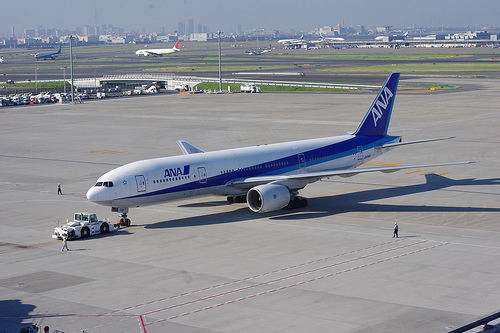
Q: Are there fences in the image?
A: No, there are no fences.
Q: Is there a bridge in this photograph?
A: Yes, there is a bridge.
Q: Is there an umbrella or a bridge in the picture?
A: Yes, there is a bridge.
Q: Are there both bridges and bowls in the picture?
A: No, there is a bridge but no bowls.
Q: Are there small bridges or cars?
A: Yes, there is a small bridge.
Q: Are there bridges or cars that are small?
A: Yes, the bridge is small.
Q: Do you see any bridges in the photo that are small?
A: Yes, there is a small bridge.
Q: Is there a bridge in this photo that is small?
A: Yes, there is a bridge that is small.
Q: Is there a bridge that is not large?
A: Yes, there is a small bridge.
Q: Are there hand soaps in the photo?
A: No, there are no hand soaps.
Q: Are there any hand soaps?
A: No, there are no hand soaps.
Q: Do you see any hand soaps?
A: No, there are no hand soaps.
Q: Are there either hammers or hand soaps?
A: No, there are no hand soaps or hammers.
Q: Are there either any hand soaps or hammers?
A: No, there are no hand soaps or hammers.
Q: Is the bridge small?
A: Yes, the bridge is small.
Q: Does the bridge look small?
A: Yes, the bridge is small.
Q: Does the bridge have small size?
A: Yes, the bridge is small.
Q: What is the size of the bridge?
A: The bridge is small.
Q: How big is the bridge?
A: The bridge is small.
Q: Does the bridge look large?
A: No, the bridge is small.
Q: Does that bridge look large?
A: No, the bridge is small.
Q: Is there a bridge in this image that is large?
A: No, there is a bridge but it is small.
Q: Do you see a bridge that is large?
A: No, there is a bridge but it is small.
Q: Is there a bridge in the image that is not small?
A: No, there is a bridge but it is small.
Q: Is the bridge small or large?
A: The bridge is small.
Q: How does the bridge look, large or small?
A: The bridge is small.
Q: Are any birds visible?
A: No, there are no birds.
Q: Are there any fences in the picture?
A: No, there are no fences.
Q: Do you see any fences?
A: No, there are no fences.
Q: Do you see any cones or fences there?
A: No, there are no fences or cones.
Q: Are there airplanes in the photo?
A: Yes, there is an airplane.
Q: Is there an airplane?
A: Yes, there is an airplane.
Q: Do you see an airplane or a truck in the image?
A: Yes, there is an airplane.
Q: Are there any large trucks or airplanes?
A: Yes, there is a large airplane.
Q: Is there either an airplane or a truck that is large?
A: Yes, the airplane is large.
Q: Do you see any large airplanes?
A: Yes, there is a large airplane.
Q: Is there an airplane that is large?
A: Yes, there is an airplane that is large.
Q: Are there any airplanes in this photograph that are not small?
A: Yes, there is a large airplane.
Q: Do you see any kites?
A: No, there are no kites.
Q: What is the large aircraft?
A: The aircraft is an airplane.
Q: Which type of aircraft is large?
A: The aircraft is an airplane.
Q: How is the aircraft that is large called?
A: The aircraft is an airplane.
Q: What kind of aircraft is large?
A: The aircraft is an airplane.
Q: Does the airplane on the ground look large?
A: Yes, the airplane is large.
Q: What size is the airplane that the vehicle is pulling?
A: The airplane is large.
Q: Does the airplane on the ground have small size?
A: No, the plane is large.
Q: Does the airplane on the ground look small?
A: No, the plane is large.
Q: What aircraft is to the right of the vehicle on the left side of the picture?
A: The aircraft is an airplane.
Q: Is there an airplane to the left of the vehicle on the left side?
A: No, the airplane is to the right of the vehicle.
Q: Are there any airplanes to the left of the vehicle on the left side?
A: No, the airplane is to the right of the vehicle.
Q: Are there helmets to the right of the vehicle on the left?
A: No, there is an airplane to the right of the vehicle.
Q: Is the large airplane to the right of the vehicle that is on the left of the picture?
A: Yes, the plane is to the right of the vehicle.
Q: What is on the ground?
A: The airplane is on the ground.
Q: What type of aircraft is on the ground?
A: The aircraft is an airplane.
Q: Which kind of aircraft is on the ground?
A: The aircraft is an airplane.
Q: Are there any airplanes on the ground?
A: Yes, there is an airplane on the ground.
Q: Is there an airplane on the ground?
A: Yes, there is an airplane on the ground.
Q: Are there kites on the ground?
A: No, there is an airplane on the ground.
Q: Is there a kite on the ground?
A: No, there is an airplane on the ground.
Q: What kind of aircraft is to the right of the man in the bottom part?
A: The aircraft is an airplane.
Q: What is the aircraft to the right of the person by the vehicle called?
A: The aircraft is an airplane.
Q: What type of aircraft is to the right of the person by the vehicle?
A: The aircraft is an airplane.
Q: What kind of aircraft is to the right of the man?
A: The aircraft is an airplane.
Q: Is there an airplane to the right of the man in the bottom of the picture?
A: Yes, there is an airplane to the right of the man.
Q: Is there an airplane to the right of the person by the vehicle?
A: Yes, there is an airplane to the right of the man.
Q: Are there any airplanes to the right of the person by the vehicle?
A: Yes, there is an airplane to the right of the man.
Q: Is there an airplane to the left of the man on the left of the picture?
A: No, the airplane is to the right of the man.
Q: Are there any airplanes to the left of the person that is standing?
A: No, the airplane is to the right of the man.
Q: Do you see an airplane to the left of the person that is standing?
A: No, the airplane is to the right of the man.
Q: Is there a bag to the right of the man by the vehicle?
A: No, there is an airplane to the right of the man.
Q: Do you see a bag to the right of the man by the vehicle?
A: No, there is an airplane to the right of the man.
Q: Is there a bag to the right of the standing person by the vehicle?
A: No, there is an airplane to the right of the man.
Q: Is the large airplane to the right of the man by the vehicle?
A: Yes, the airplane is to the right of the man.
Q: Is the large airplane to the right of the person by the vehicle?
A: Yes, the airplane is to the right of the man.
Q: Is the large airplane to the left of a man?
A: No, the airplane is to the right of a man.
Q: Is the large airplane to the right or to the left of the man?
A: The airplane is to the right of the man.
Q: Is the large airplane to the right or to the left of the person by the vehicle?
A: The airplane is to the right of the man.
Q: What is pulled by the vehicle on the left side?
A: The airplane is pulled by the vehicle.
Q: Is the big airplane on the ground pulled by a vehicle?
A: Yes, the airplane is pulled by a vehicle.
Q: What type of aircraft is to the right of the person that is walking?
A: The aircraft is an airplane.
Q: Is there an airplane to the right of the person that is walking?
A: Yes, there is an airplane to the right of the person.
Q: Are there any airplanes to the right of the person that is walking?
A: Yes, there is an airplane to the right of the person.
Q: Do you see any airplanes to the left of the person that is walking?
A: No, the airplane is to the right of the person.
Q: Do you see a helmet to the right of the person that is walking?
A: No, there is an airplane to the right of the person.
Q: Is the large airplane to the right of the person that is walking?
A: Yes, the airplane is to the right of the person.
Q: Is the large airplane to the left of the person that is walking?
A: No, the plane is to the right of the person.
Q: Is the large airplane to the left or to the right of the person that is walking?
A: The plane is to the right of the person.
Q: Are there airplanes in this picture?
A: Yes, there are airplanes.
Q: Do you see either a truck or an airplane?
A: Yes, there are airplanes.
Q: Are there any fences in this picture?
A: No, there are no fences.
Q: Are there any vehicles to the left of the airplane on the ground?
A: Yes, there is a vehicle to the left of the plane.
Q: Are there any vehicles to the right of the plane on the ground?
A: No, the vehicle is to the left of the plane.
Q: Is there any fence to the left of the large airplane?
A: No, there is a vehicle to the left of the airplane.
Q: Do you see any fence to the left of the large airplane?
A: No, there is a vehicle to the left of the airplane.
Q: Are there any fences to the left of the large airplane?
A: No, there is a vehicle to the left of the airplane.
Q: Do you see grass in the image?
A: Yes, there is grass.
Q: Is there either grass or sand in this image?
A: Yes, there is grass.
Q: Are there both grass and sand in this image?
A: No, there is grass but no sand.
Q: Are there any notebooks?
A: No, there are no notebooks.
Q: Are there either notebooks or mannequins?
A: No, there are no notebooks or mannequins.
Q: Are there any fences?
A: No, there are no fences.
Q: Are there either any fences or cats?
A: No, there are no fences or cats.